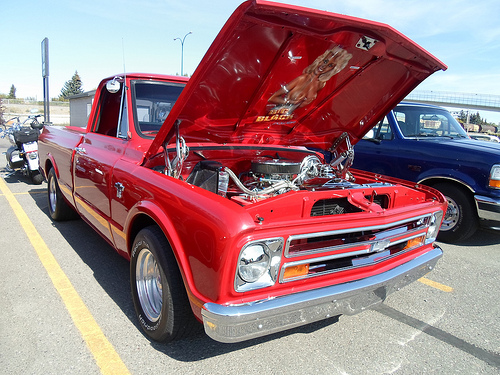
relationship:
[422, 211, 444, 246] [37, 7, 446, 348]
headlight on car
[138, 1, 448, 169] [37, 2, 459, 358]
hood on truck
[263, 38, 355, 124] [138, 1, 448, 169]
woman on hood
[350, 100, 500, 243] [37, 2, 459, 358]
car beside truck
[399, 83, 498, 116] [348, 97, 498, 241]
overpass behind truck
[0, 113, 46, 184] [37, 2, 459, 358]
motorcycle parked behind truck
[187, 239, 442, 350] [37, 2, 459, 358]
bumper on truck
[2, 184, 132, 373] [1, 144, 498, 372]
line in lot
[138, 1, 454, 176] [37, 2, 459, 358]
hood on truck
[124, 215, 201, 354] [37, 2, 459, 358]
tire on truck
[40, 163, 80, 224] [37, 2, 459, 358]
tire on truck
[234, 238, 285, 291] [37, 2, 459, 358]
headlight on truck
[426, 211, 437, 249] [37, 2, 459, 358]
headlight on truck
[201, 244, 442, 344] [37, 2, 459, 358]
bumper on truck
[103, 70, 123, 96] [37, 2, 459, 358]
mirror on truck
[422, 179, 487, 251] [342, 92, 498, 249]
wheel on truck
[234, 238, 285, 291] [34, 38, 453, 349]
headlight of truck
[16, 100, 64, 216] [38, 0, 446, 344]
motorcycle behind car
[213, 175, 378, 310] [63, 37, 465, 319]
headlight on car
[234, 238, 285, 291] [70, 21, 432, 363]
headlight on car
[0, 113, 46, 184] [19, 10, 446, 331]
motorcycle behind truck